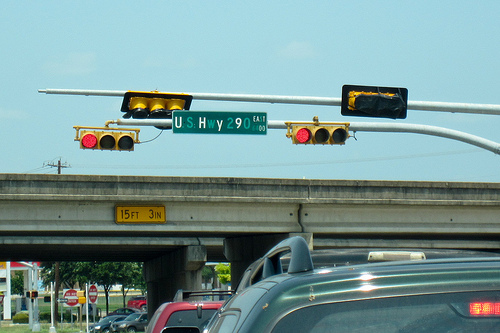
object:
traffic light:
[115, 136, 137, 152]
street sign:
[172, 111, 268, 133]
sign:
[58, 288, 85, 309]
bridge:
[0, 173, 499, 320]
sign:
[113, 205, 171, 225]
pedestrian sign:
[24, 291, 39, 300]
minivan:
[162, 232, 500, 333]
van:
[147, 298, 239, 333]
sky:
[0, 0, 499, 187]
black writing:
[118, 208, 124, 222]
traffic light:
[328, 126, 349, 145]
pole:
[117, 117, 500, 155]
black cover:
[350, 93, 405, 121]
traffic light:
[340, 83, 408, 120]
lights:
[328, 126, 348, 145]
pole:
[37, 84, 500, 116]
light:
[79, 132, 98, 151]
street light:
[122, 92, 149, 121]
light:
[297, 128, 313, 142]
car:
[126, 296, 150, 310]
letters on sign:
[157, 210, 164, 218]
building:
[0, 261, 42, 316]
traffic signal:
[98, 133, 117, 151]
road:
[0, 322, 499, 333]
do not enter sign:
[64, 289, 83, 305]